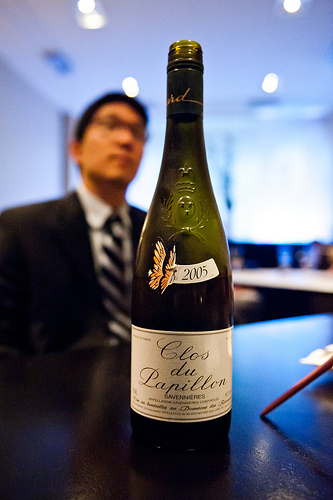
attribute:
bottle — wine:
[121, 36, 240, 485]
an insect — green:
[139, 243, 181, 292]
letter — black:
[156, 339, 181, 358]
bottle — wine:
[131, 39, 230, 481]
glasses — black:
[89, 112, 150, 146]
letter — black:
[136, 365, 161, 392]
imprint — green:
[155, 177, 217, 231]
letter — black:
[136, 366, 159, 387]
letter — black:
[155, 379, 164, 390]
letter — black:
[163, 381, 178, 394]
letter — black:
[180, 379, 189, 389]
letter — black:
[162, 376, 185, 402]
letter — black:
[200, 370, 216, 393]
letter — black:
[169, 357, 194, 380]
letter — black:
[188, 346, 202, 364]